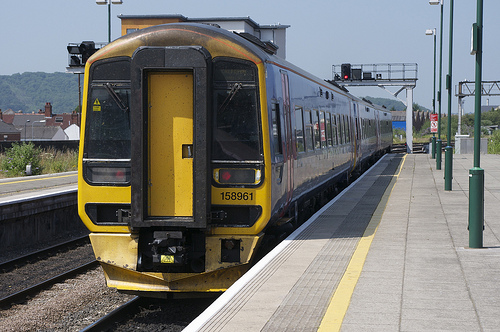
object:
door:
[145, 69, 196, 216]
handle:
[181, 142, 197, 159]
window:
[83, 80, 129, 162]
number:
[218, 190, 225, 200]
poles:
[469, 0, 486, 250]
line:
[314, 151, 407, 331]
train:
[76, 22, 392, 300]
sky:
[0, 0, 498, 115]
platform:
[183, 150, 498, 331]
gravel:
[28, 298, 49, 307]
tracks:
[0, 257, 148, 331]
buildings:
[0, 102, 81, 154]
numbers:
[240, 192, 248, 201]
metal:
[112, 208, 130, 224]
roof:
[88, 21, 266, 61]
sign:
[428, 113, 439, 134]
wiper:
[103, 82, 129, 110]